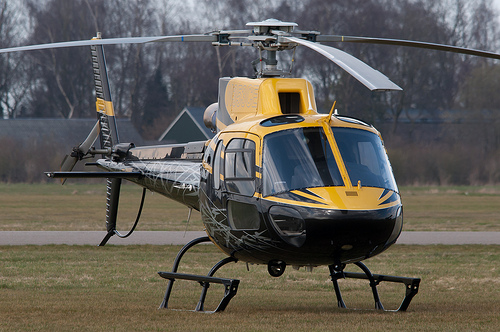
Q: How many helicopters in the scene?
A: One.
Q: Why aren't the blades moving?
A: It's parked.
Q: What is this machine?
A: A helicopter.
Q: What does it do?
A: It flies.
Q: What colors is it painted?
A: Yellow and black.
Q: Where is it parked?
A: In a field.